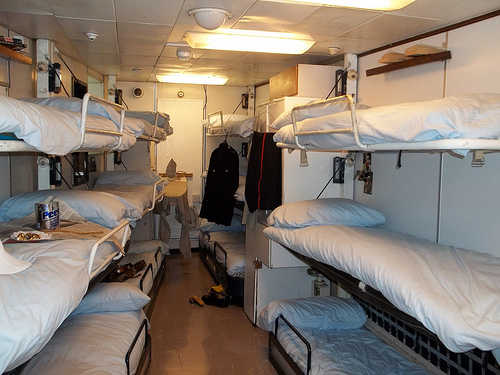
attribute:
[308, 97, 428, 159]
bed — bottom, middle, top, white, back, small, bunk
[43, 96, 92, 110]
pillow — white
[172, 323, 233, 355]
floor — glossy, brown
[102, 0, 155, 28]
ceiling — white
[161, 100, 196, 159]
door — one, white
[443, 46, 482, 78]
wall — white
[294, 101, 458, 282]
beds — 12, three, inside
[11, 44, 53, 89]
clothes — black, hanging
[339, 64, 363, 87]
pole — small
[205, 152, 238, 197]
coat — hanging, large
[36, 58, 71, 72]
camera — black